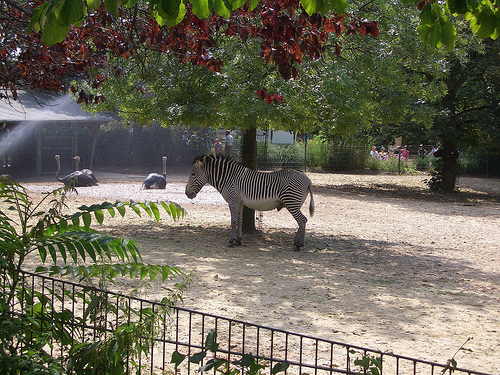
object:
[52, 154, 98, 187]
ostriche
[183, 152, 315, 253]
zebra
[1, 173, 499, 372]
ground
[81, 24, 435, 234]
tree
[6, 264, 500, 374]
fence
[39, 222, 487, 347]
shadow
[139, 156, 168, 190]
bird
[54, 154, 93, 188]
bird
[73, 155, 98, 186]
bird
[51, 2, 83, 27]
leaves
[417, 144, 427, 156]
people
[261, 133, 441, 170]
fence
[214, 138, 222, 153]
people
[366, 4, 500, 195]
tree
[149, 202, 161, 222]
leaves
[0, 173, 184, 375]
bush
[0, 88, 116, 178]
building